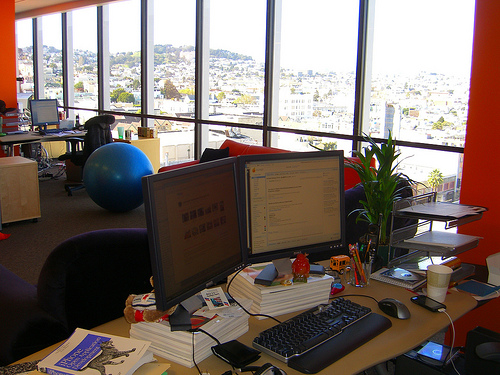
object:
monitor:
[238, 153, 345, 258]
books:
[226, 259, 333, 320]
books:
[127, 292, 252, 370]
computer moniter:
[29, 98, 64, 134]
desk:
[0, 126, 89, 147]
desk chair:
[32, 228, 149, 343]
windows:
[196, 0, 472, 147]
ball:
[81, 141, 154, 213]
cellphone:
[410, 294, 447, 312]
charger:
[434, 307, 460, 372]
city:
[218, 55, 472, 141]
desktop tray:
[379, 192, 488, 285]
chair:
[63, 113, 131, 196]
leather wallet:
[211, 338, 263, 368]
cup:
[350, 255, 373, 287]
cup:
[427, 264, 453, 303]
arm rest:
[286, 312, 393, 375]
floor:
[3, 177, 148, 289]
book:
[37, 326, 157, 375]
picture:
[77, 340, 137, 375]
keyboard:
[252, 295, 371, 361]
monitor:
[142, 156, 241, 303]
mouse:
[378, 298, 412, 320]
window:
[64, 5, 99, 109]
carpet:
[0, 164, 145, 281]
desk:
[5, 252, 480, 375]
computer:
[143, 147, 350, 333]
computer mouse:
[378, 297, 411, 319]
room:
[5, 8, 496, 373]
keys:
[300, 331, 329, 350]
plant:
[344, 128, 429, 244]